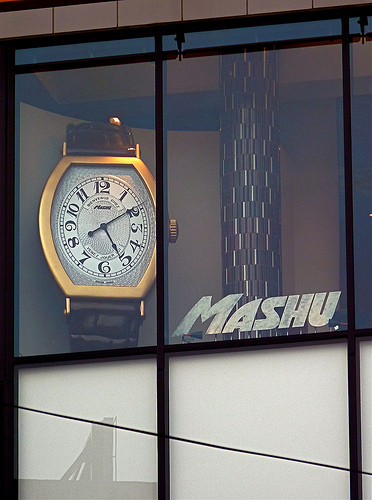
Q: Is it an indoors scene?
A: Yes, it is indoors.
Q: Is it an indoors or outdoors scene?
A: It is indoors.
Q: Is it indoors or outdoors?
A: It is indoors.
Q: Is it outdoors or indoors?
A: It is indoors.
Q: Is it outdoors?
A: No, it is indoors.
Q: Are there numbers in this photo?
A: Yes, there are numbers.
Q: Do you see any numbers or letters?
A: Yes, there are numbers.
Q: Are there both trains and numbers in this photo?
A: No, there are numbers but no trains.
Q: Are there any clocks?
A: Yes, there is a clock.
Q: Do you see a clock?
A: Yes, there is a clock.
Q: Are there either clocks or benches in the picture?
A: Yes, there is a clock.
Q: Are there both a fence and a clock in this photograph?
A: No, there is a clock but no fences.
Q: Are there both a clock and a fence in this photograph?
A: No, there is a clock but no fences.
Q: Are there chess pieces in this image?
A: No, there are no chess pieces.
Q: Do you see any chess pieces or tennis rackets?
A: No, there are no chess pieces or tennis rackets.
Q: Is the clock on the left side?
A: Yes, the clock is on the left of the image.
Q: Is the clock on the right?
A: No, the clock is on the left of the image.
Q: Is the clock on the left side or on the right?
A: The clock is on the left of the image.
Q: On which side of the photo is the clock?
A: The clock is on the left of the image.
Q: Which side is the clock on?
A: The clock is on the left of the image.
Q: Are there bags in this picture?
A: No, there are no bags.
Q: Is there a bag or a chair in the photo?
A: No, there are no bags or chairs.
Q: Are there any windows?
A: Yes, there is a window.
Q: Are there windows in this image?
A: Yes, there is a window.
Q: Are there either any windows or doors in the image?
A: Yes, there is a window.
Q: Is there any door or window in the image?
A: Yes, there is a window.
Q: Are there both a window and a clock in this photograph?
A: Yes, there are both a window and a clock.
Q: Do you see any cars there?
A: No, there are no cars.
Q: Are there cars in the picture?
A: No, there are no cars.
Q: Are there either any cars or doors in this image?
A: No, there are no cars or doors.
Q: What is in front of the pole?
A: The window is in front of the pole.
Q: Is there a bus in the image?
A: No, there are no buses.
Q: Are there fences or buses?
A: No, there are no buses or fences.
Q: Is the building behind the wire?
A: Yes, the building is behind the wire.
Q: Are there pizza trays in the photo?
A: No, there are no pizza trays.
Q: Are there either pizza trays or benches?
A: No, there are no pizza trays or benches.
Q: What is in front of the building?
A: The wire is in front of the building.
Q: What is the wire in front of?
A: The wire is in front of the building.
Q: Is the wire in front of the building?
A: Yes, the wire is in front of the building.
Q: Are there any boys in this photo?
A: No, there are no boys.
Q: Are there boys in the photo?
A: No, there are no boys.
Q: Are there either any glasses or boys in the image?
A: No, there are no boys or glasses.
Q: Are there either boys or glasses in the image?
A: No, there are no boys or glasses.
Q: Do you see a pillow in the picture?
A: No, there are no pillows.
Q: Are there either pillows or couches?
A: No, there are no pillows or couches.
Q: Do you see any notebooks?
A: No, there are no notebooks.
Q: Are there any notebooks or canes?
A: No, there are no notebooks or canes.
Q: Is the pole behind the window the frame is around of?
A: Yes, the pole is behind the window.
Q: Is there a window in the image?
A: Yes, there is a window.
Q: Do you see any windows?
A: Yes, there is a window.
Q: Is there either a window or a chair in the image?
A: Yes, there is a window.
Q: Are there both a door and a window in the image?
A: No, there is a window but no doors.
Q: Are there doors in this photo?
A: No, there are no doors.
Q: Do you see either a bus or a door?
A: No, there are no doors or buses.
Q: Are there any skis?
A: No, there are no skis.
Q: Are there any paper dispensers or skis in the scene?
A: No, there are no skis or paper dispensers.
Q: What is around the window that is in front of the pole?
A: The frame is around the window.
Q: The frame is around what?
A: The frame is around the window.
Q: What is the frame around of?
A: The frame is around the window.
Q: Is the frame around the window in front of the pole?
A: Yes, the frame is around the window.